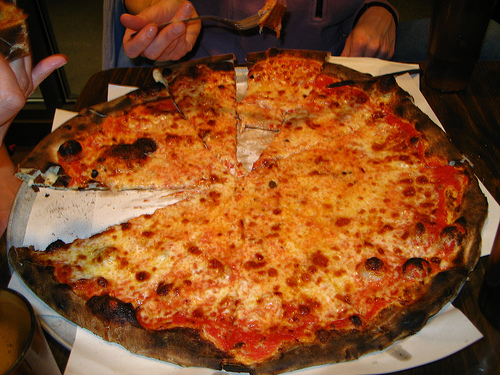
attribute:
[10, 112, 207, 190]
slice — burnt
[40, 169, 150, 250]
grease stain — small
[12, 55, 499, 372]
cardboard — white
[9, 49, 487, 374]
pizza — large, cheese, bitten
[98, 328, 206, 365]
edge — brown, baked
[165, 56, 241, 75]
crust — burnt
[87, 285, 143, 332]
spot — black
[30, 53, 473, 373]
table — dark, brown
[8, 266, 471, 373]
pizza crust — dark brown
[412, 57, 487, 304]
pizza crust — dark brown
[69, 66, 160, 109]
table — wooden, brown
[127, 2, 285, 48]
fork — small and  silver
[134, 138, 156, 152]
spot — dark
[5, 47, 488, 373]
cheese pizza — whole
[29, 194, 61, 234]
plate — white